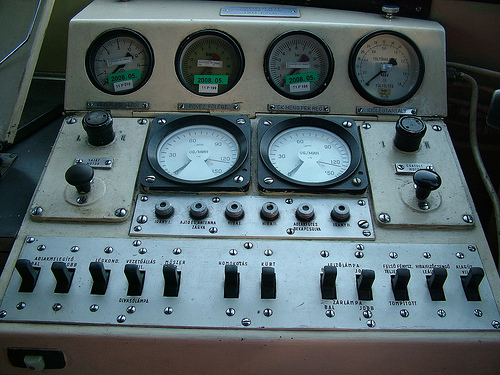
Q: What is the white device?
A: The device is a control panel.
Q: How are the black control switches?
A: They are in a row.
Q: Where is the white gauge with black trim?
A: In the middle of the control panel.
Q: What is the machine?
A: Electronic.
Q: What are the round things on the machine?
A: Displays.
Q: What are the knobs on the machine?
A: Switches.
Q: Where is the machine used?
A: On a ship.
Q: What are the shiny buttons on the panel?
A: Plungers.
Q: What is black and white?
A: Console.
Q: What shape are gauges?
A: Round.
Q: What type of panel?
A: Control.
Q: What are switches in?
A: Rows.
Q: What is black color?
A: Switches.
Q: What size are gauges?
A: Large.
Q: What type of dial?
A: Analog.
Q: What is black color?
A: Knobs.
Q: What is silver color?
A: Panel.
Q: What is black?
A: Switches.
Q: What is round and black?
A: Buttons.